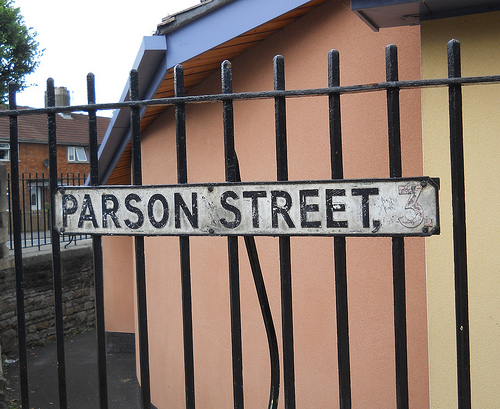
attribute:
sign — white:
[54, 176, 441, 237]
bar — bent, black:
[234, 151, 281, 408]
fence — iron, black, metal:
[3, 38, 497, 405]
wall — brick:
[1, 140, 101, 235]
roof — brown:
[1, 102, 112, 146]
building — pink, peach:
[97, 0, 428, 407]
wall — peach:
[102, 3, 426, 408]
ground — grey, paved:
[2, 331, 140, 408]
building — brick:
[0, 104, 112, 236]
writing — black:
[62, 189, 380, 230]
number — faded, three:
[396, 185, 425, 230]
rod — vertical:
[8, 79, 33, 408]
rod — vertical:
[445, 38, 473, 405]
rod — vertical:
[221, 58, 250, 408]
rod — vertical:
[46, 77, 70, 408]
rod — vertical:
[86, 73, 110, 408]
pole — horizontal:
[2, 75, 498, 117]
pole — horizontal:
[0, 176, 87, 184]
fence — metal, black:
[1, 172, 94, 252]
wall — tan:
[419, 9, 499, 408]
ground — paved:
[7, 230, 93, 258]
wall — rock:
[1, 245, 98, 354]